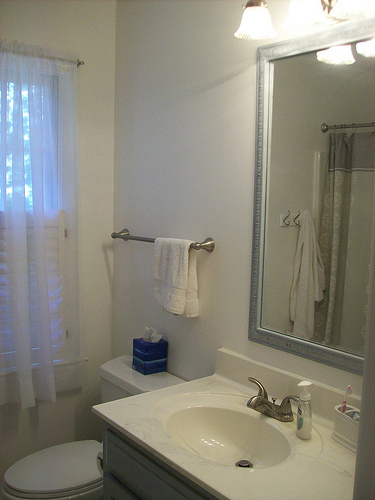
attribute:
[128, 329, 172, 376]
box — blue, square, on toilet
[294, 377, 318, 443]
bottle — soap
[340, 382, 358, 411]
toothbrush — red, white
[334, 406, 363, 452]
holder — white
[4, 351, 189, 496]
commode — white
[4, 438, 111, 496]
lid — down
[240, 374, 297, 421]
faucet — metal, silver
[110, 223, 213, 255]
bar — metal, hung, silver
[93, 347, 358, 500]
sink — off white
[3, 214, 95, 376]
shutters — white, indoor, in a window, wooden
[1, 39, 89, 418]
shears — white, long, sheer, on window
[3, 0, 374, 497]
bathroom — small, white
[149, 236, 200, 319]
towel — white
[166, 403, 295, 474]
basin — oval shaped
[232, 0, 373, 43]
lighting — overhead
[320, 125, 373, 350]
shower curtain — tan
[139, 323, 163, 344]
tissue — white